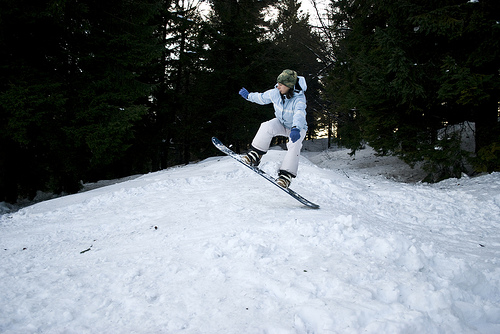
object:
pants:
[250, 117, 307, 177]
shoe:
[276, 170, 293, 188]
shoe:
[240, 145, 262, 165]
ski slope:
[0, 137, 499, 333]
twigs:
[79, 246, 96, 254]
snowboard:
[202, 134, 329, 216]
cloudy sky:
[300, 2, 332, 27]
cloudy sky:
[195, 0, 211, 17]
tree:
[312, 0, 499, 179]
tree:
[158, 0, 330, 165]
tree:
[2, 0, 182, 210]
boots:
[240, 150, 294, 188]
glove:
[238, 87, 250, 99]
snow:
[3, 174, 498, 331]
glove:
[290, 127, 300, 143]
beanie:
[277, 69, 297, 89]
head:
[275, 69, 297, 95]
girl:
[238, 68, 309, 189]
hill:
[0, 129, 499, 333]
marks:
[230, 211, 368, 314]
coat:
[246, 76, 309, 131]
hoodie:
[247, 75, 309, 133]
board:
[208, 136, 321, 212]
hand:
[291, 128, 301, 143]